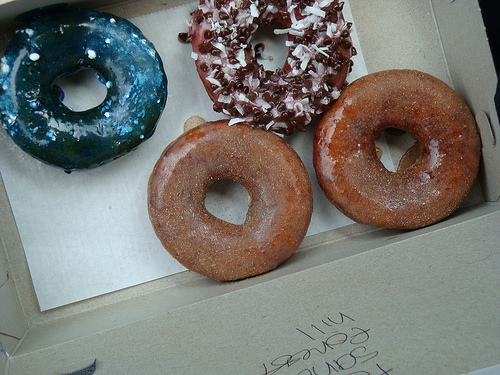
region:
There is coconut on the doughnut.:
[166, 10, 351, 115]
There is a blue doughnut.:
[3, 16, 161, 159]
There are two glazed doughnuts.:
[148, 63, 475, 283]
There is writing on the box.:
[208, 294, 418, 374]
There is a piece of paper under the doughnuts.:
[10, 195, 160, 317]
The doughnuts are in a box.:
[361, 242, 495, 373]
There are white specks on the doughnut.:
[26, 42, 45, 70]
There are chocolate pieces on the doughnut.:
[205, 19, 265, 118]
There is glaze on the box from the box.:
[366, 117, 429, 180]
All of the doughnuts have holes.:
[8, 8, 494, 234]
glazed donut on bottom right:
[317, 63, 482, 227]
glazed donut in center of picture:
[146, 121, 315, 283]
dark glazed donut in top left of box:
[2, 5, 167, 169]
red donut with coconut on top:
[187, 0, 356, 125]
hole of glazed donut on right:
[371, 118, 423, 175]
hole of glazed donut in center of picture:
[199, 170, 259, 230]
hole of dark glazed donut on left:
[51, 61, 112, 112]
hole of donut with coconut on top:
[244, 16, 299, 76]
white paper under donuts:
[4, 6, 391, 309]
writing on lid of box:
[255, 301, 402, 373]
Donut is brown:
[140, 110, 322, 289]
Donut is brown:
[307, 63, 490, 245]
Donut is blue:
[1, 7, 176, 182]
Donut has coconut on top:
[179, 0, 369, 143]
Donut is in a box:
[1, 0, 497, 370]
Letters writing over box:
[237, 305, 413, 372]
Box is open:
[7, 5, 495, 370]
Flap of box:
[0, 211, 499, 372]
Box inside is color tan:
[3, 1, 496, 373]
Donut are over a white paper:
[0, 0, 417, 318]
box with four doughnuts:
[18, 8, 488, 256]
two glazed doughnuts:
[165, 77, 485, 297]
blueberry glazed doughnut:
[6, 8, 163, 168]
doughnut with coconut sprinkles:
[166, 4, 396, 144]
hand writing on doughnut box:
[229, 307, 376, 374]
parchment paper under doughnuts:
[8, 29, 423, 294]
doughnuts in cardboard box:
[2, 166, 498, 365]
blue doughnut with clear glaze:
[5, 11, 186, 166]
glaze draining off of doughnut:
[164, 94, 219, 156]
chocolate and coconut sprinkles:
[184, 4, 363, 139]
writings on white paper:
[283, 310, 403, 367]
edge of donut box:
[117, 306, 238, 338]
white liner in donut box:
[17, 247, 96, 304]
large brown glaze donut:
[158, 130, 326, 283]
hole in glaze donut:
[207, 174, 254, 236]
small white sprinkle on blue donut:
[78, 48, 117, 72]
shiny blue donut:
[3, 21, 254, 146]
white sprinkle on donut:
[198, 64, 240, 94]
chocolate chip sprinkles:
[194, 29, 242, 84]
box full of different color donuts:
[41, 27, 485, 233]